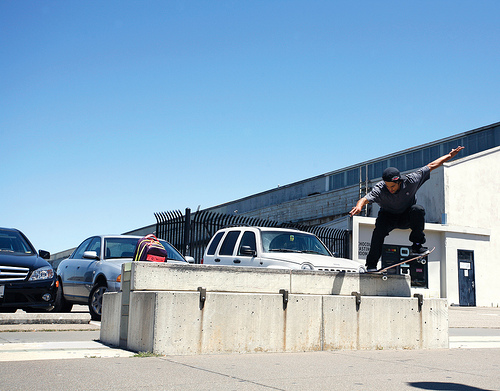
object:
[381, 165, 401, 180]
hat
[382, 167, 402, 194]
head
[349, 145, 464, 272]
guy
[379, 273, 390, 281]
wheel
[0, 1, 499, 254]
sky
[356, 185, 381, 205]
arm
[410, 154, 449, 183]
arm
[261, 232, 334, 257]
window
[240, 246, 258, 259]
mirror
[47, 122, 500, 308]
building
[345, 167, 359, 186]
windows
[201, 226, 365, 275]
jeep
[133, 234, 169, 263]
part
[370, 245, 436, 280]
skateboard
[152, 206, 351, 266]
fence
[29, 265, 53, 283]
headlight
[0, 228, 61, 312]
car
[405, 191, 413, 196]
symbol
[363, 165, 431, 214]
shirt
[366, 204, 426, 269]
pants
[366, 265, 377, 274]
sneaker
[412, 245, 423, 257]
sneaker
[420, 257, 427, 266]
wheel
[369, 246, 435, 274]
board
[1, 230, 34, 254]
window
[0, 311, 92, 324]
block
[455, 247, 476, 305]
door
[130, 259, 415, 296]
slab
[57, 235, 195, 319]
car